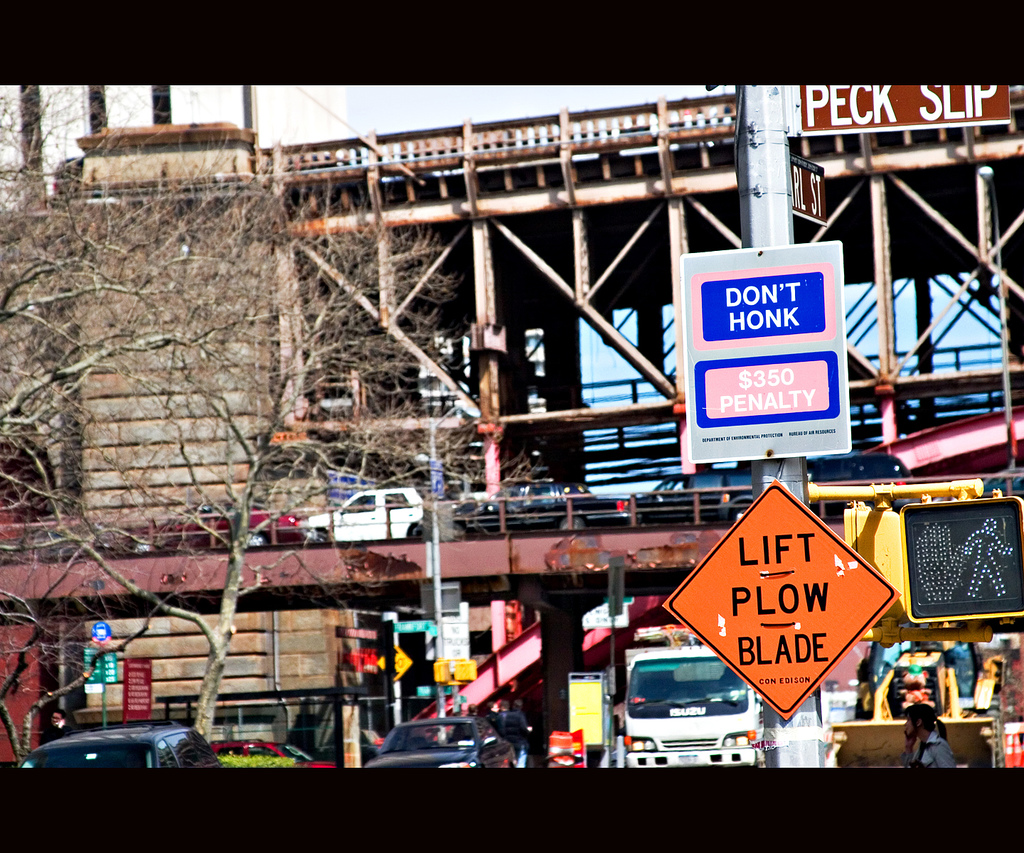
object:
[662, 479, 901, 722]
sign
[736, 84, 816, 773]
pole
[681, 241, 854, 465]
poster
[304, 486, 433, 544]
cars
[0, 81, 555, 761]
tree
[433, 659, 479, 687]
light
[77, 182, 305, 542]
support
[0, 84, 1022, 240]
bridge